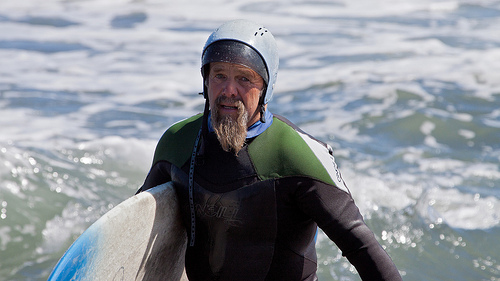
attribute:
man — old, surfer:
[139, 25, 402, 280]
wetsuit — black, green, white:
[132, 114, 401, 280]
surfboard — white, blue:
[48, 185, 189, 281]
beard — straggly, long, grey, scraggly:
[214, 110, 250, 154]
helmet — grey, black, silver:
[196, 18, 276, 105]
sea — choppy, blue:
[1, 1, 496, 280]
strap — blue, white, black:
[185, 113, 204, 245]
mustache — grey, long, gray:
[213, 98, 250, 120]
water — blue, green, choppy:
[1, 1, 497, 280]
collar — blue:
[207, 112, 275, 134]